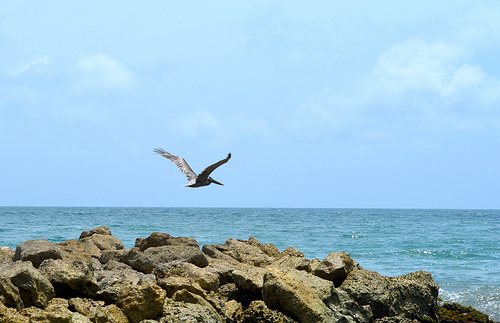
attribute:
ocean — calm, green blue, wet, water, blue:
[1, 204, 499, 323]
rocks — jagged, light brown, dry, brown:
[260, 264, 334, 322]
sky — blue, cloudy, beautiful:
[1, 2, 500, 212]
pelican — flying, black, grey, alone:
[152, 145, 233, 193]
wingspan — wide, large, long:
[150, 145, 233, 180]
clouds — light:
[290, 36, 499, 138]